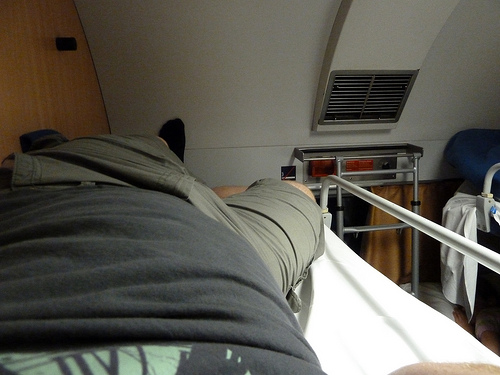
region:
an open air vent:
[326, 62, 415, 134]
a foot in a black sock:
[160, 117, 191, 164]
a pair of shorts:
[7, 133, 326, 291]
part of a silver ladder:
[326, 154, 434, 289]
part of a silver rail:
[319, 166, 497, 299]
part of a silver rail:
[476, 159, 499, 193]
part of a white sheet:
[440, 184, 476, 314]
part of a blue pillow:
[440, 117, 499, 188]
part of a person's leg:
[207, 173, 317, 204]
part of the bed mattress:
[296, 228, 498, 373]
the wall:
[241, 48, 416, 105]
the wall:
[196, 28, 282, 178]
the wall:
[181, 2, 261, 116]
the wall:
[206, 34, 348, 236]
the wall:
[217, 28, 262, 134]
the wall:
[202, 19, 249, 161]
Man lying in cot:
[25, 88, 492, 370]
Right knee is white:
[260, 150, 323, 228]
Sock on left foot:
[153, 108, 202, 169]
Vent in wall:
[319, 60, 427, 132]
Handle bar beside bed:
[328, 174, 496, 275]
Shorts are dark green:
[79, 133, 331, 250]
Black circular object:
[55, 30, 82, 60]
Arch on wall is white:
[345, 9, 426, 156]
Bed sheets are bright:
[321, 249, 436, 373]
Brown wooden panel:
[20, 21, 105, 121]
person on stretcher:
[1, 112, 330, 372]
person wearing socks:
[139, 97, 238, 189]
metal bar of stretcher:
[311, 150, 496, 304]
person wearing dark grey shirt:
[26, 180, 290, 367]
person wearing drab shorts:
[33, 119, 347, 284]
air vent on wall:
[317, 71, 427, 126]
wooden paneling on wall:
[6, 8, 128, 173]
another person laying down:
[435, 257, 498, 337]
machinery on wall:
[294, 148, 444, 192]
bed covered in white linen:
[216, 188, 497, 372]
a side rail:
[377, 179, 422, 333]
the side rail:
[321, 183, 495, 308]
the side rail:
[354, 77, 496, 287]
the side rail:
[380, 182, 468, 370]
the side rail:
[345, 157, 427, 318]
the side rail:
[296, 97, 449, 356]